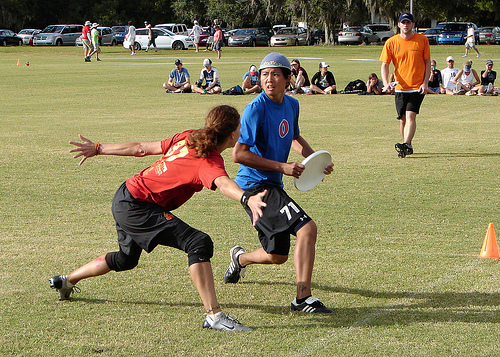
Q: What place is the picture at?
A: It is at the field.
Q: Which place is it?
A: It is a field.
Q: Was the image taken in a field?
A: Yes, it was taken in a field.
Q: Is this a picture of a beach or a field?
A: It is showing a field.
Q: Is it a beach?
A: No, it is a field.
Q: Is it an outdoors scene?
A: Yes, it is outdoors.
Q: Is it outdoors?
A: Yes, it is outdoors.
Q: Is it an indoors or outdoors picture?
A: It is outdoors.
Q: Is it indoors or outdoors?
A: It is outdoors.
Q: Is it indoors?
A: No, it is outdoors.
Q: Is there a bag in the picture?
A: No, there are no bags.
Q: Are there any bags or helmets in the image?
A: No, there are no bags or helmets.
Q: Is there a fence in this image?
A: No, there are no fences.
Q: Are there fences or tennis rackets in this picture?
A: No, there are no fences or tennis rackets.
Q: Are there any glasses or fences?
A: No, there are no glasses or fences.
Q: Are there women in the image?
A: Yes, there is a woman.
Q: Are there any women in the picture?
A: Yes, there is a woman.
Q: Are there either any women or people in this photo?
A: Yes, there is a woman.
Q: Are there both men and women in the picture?
A: Yes, there are both a woman and a man.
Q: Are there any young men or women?
A: Yes, there is a young woman.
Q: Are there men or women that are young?
A: Yes, the woman is young.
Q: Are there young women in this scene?
A: Yes, there is a young woman.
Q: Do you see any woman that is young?
A: Yes, there is a woman that is young.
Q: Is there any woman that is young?
A: Yes, there is a woman that is young.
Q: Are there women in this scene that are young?
A: Yes, there is a woman that is young.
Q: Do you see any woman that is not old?
A: Yes, there is an young woman.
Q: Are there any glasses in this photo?
A: No, there are no glasses.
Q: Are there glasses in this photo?
A: No, there are no glasses.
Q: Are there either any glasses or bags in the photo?
A: No, there are no glasses or bags.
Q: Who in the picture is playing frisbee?
A: The woman is playing frisbee.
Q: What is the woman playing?
A: The woman is playing frisbee.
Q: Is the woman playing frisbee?
A: Yes, the woman is playing frisbee.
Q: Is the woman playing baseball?
A: No, the woman is playing frisbee.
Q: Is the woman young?
A: Yes, the woman is young.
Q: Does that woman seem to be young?
A: Yes, the woman is young.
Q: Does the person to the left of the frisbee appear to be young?
A: Yes, the woman is young.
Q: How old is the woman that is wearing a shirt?
A: The woman is young.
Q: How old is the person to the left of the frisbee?
A: The woman is young.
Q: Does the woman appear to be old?
A: No, the woman is young.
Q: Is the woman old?
A: No, the woman is young.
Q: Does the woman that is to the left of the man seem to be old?
A: No, the woman is young.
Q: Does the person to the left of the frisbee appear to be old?
A: No, the woman is young.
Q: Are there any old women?
A: No, there is a woman but she is young.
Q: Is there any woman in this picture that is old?
A: No, there is a woman but she is young.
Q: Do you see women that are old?
A: No, there is a woman but she is young.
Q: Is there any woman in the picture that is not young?
A: No, there is a woman but she is young.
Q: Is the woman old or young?
A: The woman is young.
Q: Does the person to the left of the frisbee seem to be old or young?
A: The woman is young.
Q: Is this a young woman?
A: Yes, this is a young woman.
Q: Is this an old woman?
A: No, this is a young woman.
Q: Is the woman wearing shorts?
A: Yes, the woman is wearing shorts.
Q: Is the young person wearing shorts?
A: Yes, the woman is wearing shorts.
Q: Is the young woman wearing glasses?
A: No, the woman is wearing shorts.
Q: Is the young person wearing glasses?
A: No, the woman is wearing shorts.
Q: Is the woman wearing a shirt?
A: Yes, the woman is wearing a shirt.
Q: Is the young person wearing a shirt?
A: Yes, the woman is wearing a shirt.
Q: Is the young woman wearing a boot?
A: No, the woman is wearing a shirt.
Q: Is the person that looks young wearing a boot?
A: No, the woman is wearing a shirt.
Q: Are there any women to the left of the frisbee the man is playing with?
A: Yes, there is a woman to the left of the frisbee.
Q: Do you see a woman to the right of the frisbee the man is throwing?
A: No, the woman is to the left of the frisbee.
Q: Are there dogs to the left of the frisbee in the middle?
A: No, there is a woman to the left of the frisbee.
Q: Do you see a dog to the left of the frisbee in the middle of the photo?
A: No, there is a woman to the left of the frisbee.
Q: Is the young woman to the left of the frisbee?
A: Yes, the woman is to the left of the frisbee.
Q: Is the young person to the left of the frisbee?
A: Yes, the woman is to the left of the frisbee.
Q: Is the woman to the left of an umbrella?
A: No, the woman is to the left of the frisbee.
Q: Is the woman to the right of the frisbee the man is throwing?
A: No, the woman is to the left of the frisbee.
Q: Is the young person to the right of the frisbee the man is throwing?
A: No, the woman is to the left of the frisbee.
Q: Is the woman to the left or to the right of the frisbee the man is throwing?
A: The woman is to the left of the frisbee.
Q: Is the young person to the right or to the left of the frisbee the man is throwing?
A: The woman is to the left of the frisbee.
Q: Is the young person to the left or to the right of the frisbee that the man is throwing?
A: The woman is to the left of the frisbee.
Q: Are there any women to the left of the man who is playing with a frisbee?
A: Yes, there is a woman to the left of the man.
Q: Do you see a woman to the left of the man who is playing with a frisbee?
A: Yes, there is a woman to the left of the man.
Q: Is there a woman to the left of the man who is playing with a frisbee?
A: Yes, there is a woman to the left of the man.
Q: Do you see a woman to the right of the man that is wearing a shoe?
A: No, the woman is to the left of the man.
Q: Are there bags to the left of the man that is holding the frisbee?
A: No, there is a woman to the left of the man.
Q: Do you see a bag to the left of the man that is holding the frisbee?
A: No, there is a woman to the left of the man.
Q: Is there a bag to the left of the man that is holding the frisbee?
A: No, there is a woman to the left of the man.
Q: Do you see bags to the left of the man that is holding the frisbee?
A: No, there is a woman to the left of the man.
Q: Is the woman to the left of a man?
A: Yes, the woman is to the left of a man.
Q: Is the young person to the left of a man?
A: Yes, the woman is to the left of a man.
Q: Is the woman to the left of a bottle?
A: No, the woman is to the left of a man.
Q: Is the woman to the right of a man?
A: No, the woman is to the left of a man.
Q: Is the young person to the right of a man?
A: No, the woman is to the left of a man.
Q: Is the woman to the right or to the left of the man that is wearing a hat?
A: The woman is to the left of the man.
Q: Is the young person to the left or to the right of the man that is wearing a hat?
A: The woman is to the left of the man.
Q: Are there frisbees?
A: Yes, there is a frisbee.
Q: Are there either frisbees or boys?
A: Yes, there is a frisbee.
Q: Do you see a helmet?
A: No, there are no helmets.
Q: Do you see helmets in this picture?
A: No, there are no helmets.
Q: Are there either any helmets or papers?
A: No, there are no helmets or papers.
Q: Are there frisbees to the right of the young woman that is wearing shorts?
A: Yes, there is a frisbee to the right of the woman.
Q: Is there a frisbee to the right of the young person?
A: Yes, there is a frisbee to the right of the woman.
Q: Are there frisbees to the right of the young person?
A: Yes, there is a frisbee to the right of the woman.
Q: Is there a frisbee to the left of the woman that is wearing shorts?
A: No, the frisbee is to the right of the woman.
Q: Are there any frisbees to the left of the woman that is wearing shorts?
A: No, the frisbee is to the right of the woman.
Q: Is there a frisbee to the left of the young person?
A: No, the frisbee is to the right of the woman.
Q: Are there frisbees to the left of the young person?
A: No, the frisbee is to the right of the woman.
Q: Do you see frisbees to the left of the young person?
A: No, the frisbee is to the right of the woman.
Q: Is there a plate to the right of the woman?
A: No, there is a frisbee to the right of the woman.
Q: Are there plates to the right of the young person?
A: No, there is a frisbee to the right of the woman.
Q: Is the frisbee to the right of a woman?
A: Yes, the frisbee is to the right of a woman.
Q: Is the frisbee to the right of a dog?
A: No, the frisbee is to the right of a woman.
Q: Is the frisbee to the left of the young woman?
A: No, the frisbee is to the right of the woman.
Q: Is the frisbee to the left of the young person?
A: No, the frisbee is to the right of the woman.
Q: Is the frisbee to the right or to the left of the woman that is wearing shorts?
A: The frisbee is to the right of the woman.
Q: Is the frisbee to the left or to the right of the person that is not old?
A: The frisbee is to the right of the woman.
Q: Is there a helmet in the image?
A: No, there are no helmets.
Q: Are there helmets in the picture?
A: No, there are no helmets.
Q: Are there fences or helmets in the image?
A: No, there are no helmets or fences.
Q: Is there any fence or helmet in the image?
A: No, there are no helmets or fences.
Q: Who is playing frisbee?
A: The man is playing frisbee.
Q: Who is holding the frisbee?
A: The man is holding the frisbee.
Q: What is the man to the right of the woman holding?
A: The man is holding the frisbee.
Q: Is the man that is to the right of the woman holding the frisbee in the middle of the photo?
A: Yes, the man is holding the frisbee.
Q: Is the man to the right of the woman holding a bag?
A: No, the man is holding the frisbee.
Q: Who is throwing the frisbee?
A: The man is throwing the frisbee.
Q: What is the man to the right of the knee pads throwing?
A: The man is throwing the frisbee.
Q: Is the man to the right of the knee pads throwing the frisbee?
A: Yes, the man is throwing the frisbee.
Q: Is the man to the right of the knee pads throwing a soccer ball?
A: No, the man is throwing the frisbee.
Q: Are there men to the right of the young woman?
A: Yes, there is a man to the right of the woman.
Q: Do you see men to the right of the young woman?
A: Yes, there is a man to the right of the woman.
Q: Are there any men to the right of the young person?
A: Yes, there is a man to the right of the woman.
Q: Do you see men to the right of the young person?
A: Yes, there is a man to the right of the woman.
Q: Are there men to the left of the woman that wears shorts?
A: No, the man is to the right of the woman.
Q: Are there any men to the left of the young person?
A: No, the man is to the right of the woman.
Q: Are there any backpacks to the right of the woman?
A: No, there is a man to the right of the woman.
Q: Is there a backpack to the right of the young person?
A: No, there is a man to the right of the woman.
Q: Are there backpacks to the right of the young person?
A: No, there is a man to the right of the woman.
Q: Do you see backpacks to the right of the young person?
A: No, there is a man to the right of the woman.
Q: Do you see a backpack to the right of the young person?
A: No, there is a man to the right of the woman.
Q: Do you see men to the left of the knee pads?
A: No, the man is to the right of the knee pads.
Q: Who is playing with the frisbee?
A: The man is playing with the frisbee.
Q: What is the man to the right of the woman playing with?
A: The man is playing with a frisbee.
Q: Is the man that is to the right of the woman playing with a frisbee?
A: Yes, the man is playing with a frisbee.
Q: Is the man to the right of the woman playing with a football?
A: No, the man is playing with a frisbee.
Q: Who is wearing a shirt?
A: The man is wearing a shirt.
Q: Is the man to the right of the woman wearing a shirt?
A: Yes, the man is wearing a shirt.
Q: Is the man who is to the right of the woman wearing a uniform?
A: No, the man is wearing a shirt.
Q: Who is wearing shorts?
A: The man is wearing shorts.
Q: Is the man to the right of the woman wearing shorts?
A: Yes, the man is wearing shorts.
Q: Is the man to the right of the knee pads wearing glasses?
A: No, the man is wearing shorts.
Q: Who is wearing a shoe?
A: The man is wearing a shoe.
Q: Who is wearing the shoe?
A: The man is wearing a shoe.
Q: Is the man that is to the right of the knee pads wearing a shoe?
A: Yes, the man is wearing a shoe.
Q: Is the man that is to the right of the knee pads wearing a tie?
A: No, the man is wearing a shoe.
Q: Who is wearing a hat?
A: The man is wearing a hat.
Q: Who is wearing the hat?
A: The man is wearing a hat.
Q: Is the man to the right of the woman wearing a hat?
A: Yes, the man is wearing a hat.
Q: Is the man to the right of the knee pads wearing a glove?
A: No, the man is wearing a hat.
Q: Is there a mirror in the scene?
A: No, there are no mirrors.